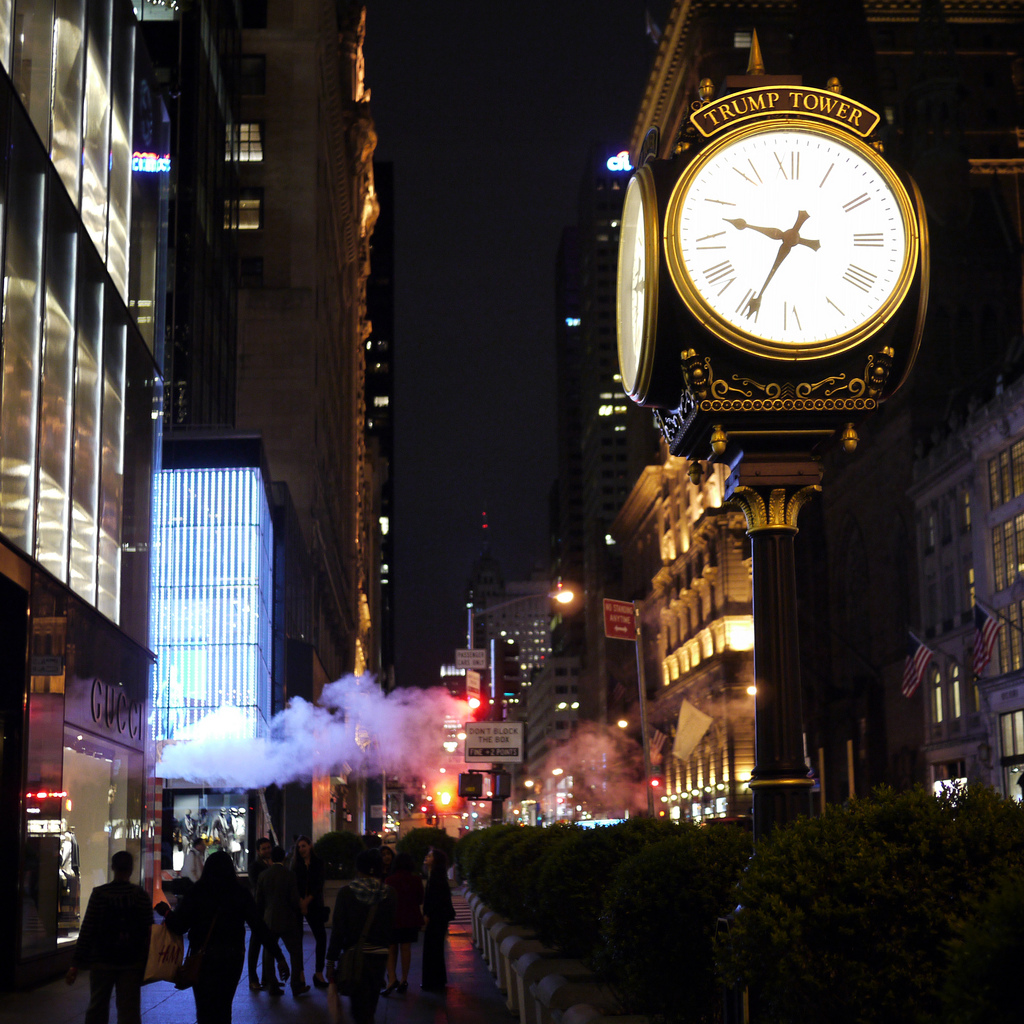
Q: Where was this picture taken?
A: Trump Tower.